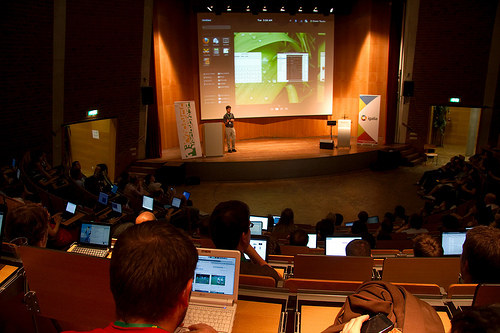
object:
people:
[121, 173, 148, 199]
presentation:
[195, 15, 338, 120]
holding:
[432, 175, 445, 188]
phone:
[425, 178, 448, 185]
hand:
[436, 178, 453, 186]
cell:
[434, 179, 444, 186]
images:
[195, 263, 233, 289]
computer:
[180, 242, 249, 301]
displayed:
[202, 269, 233, 290]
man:
[215, 101, 241, 154]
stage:
[215, 127, 348, 164]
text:
[223, 47, 267, 87]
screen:
[191, 8, 345, 123]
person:
[205, 199, 285, 283]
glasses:
[245, 219, 255, 230]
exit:
[74, 101, 114, 128]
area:
[230, 136, 489, 225]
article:
[222, 126, 241, 153]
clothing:
[222, 124, 239, 154]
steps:
[391, 131, 427, 176]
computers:
[310, 233, 377, 259]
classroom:
[3, 142, 500, 333]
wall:
[96, 0, 426, 149]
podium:
[193, 116, 236, 160]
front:
[244, 175, 330, 213]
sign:
[356, 6, 398, 153]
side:
[136, 6, 185, 159]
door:
[436, 97, 480, 151]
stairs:
[416, 194, 450, 235]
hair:
[226, 106, 228, 108]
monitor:
[182, 251, 241, 299]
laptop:
[173, 243, 244, 333]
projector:
[188, 7, 337, 23]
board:
[333, 114, 353, 154]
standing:
[169, 95, 212, 162]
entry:
[53, 111, 126, 186]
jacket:
[323, 280, 447, 333]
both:
[154, 100, 383, 170]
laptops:
[57, 214, 120, 263]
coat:
[316, 275, 449, 333]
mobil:
[347, 305, 399, 333]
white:
[205, 134, 222, 147]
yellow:
[180, 117, 191, 142]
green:
[191, 11, 352, 125]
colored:
[353, 92, 379, 113]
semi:
[143, 148, 407, 181]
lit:
[448, 96, 461, 104]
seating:
[262, 207, 420, 241]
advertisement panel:
[167, 95, 207, 163]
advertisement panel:
[351, 92, 385, 147]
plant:
[429, 98, 455, 150]